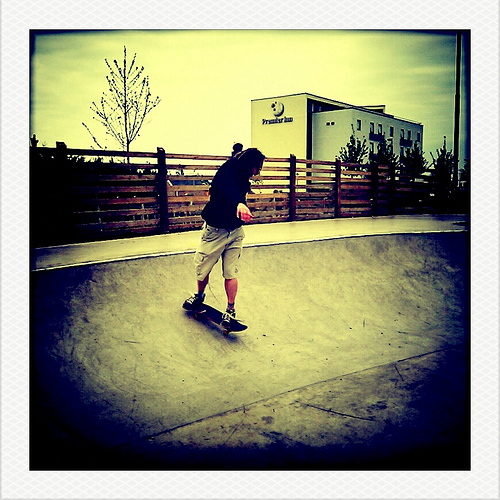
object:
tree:
[74, 46, 165, 165]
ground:
[30, 214, 470, 472]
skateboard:
[182, 302, 248, 337]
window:
[370, 123, 375, 134]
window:
[357, 119, 362, 130]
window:
[378, 124, 383, 134]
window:
[400, 147, 404, 156]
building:
[251, 92, 424, 210]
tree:
[335, 139, 365, 178]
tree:
[366, 130, 396, 178]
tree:
[396, 132, 421, 181]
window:
[388, 146, 393, 155]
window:
[400, 165, 403, 175]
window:
[400, 129, 404, 139]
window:
[407, 148, 411, 158]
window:
[408, 130, 412, 140]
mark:
[297, 392, 382, 430]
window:
[370, 143, 374, 152]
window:
[390, 126, 394, 136]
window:
[417, 133, 420, 142]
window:
[378, 145, 381, 150]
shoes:
[225, 308, 235, 318]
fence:
[31, 131, 470, 239]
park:
[30, 213, 472, 473]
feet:
[183, 294, 206, 310]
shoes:
[183, 294, 206, 311]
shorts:
[194, 225, 245, 282]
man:
[182, 147, 264, 318]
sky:
[205, 44, 386, 89]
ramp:
[28, 228, 468, 468]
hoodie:
[201, 148, 265, 230]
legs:
[222, 228, 244, 305]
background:
[75, 127, 438, 207]